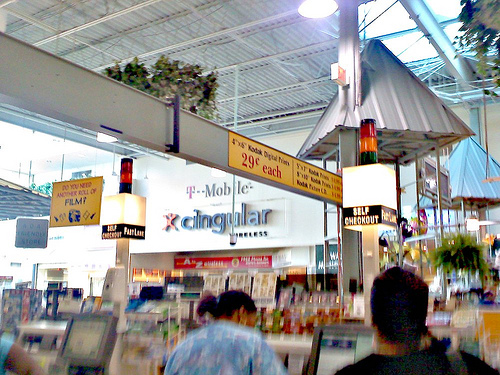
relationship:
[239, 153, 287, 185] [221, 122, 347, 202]
numbers on sign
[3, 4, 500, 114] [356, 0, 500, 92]
roof has skylight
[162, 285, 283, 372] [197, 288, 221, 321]
woman has ponytail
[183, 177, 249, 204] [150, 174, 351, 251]
t mobile on wall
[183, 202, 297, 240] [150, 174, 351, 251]
cingular wireless on wall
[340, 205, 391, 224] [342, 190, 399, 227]
self checkout on sign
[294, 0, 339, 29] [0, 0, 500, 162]
light on roof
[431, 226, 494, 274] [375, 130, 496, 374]
plant in store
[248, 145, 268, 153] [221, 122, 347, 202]
kodak on sign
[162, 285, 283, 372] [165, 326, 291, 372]
woman wearing shirt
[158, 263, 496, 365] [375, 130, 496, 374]
people near store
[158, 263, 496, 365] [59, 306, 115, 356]
people near cash register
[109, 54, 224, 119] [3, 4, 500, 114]
plants under roof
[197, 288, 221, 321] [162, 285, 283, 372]
ponytail on woman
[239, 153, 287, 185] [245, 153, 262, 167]
numbers say 29 cents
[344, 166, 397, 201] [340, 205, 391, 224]
light above self checkout